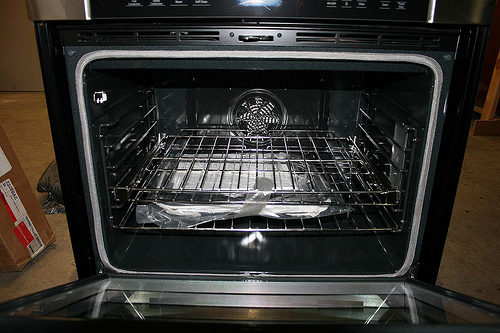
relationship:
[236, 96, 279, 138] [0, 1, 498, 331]
fan in oven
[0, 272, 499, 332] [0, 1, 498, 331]
door for oven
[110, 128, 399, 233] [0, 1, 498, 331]
racks in oven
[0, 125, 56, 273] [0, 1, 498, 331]
cardboard box next to oven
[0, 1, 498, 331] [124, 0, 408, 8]
oven has buttons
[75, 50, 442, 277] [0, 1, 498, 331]
seal on oven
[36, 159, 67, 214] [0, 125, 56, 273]
bag next to cardboard box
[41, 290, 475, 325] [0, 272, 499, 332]
window on door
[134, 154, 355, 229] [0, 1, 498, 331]
plastic bag in oven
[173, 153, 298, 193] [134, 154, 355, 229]
papers in plastic bag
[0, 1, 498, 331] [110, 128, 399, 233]
oven has racks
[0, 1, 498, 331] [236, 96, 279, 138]
oven has a fan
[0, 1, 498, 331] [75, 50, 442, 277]
oven has a seal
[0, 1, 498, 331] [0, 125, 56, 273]
oven near cardboard box